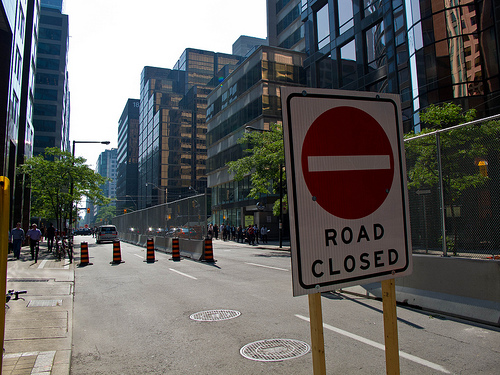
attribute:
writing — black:
[312, 218, 400, 284]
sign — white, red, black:
[277, 82, 417, 299]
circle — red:
[299, 104, 397, 220]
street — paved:
[73, 235, 499, 371]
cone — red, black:
[77, 240, 92, 265]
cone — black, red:
[106, 233, 125, 264]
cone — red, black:
[143, 235, 157, 261]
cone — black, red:
[170, 232, 181, 259]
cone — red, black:
[203, 233, 213, 263]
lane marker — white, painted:
[167, 265, 198, 281]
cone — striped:
[79, 238, 89, 265]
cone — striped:
[109, 238, 125, 265]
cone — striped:
[144, 231, 158, 262]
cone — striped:
[171, 233, 181, 262]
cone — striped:
[199, 236, 216, 260]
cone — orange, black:
[112, 233, 120, 264]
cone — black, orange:
[170, 233, 180, 261]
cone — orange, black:
[195, 231, 217, 271]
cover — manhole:
[193, 308, 238, 329]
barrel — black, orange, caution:
[197, 233, 221, 263]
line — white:
[165, 267, 199, 285]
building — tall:
[137, 34, 265, 231]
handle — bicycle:
[5, 280, 31, 303]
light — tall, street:
[100, 133, 110, 151]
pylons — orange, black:
[75, 241, 94, 269]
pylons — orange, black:
[105, 237, 124, 264]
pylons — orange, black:
[143, 233, 163, 271]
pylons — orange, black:
[168, 236, 183, 263]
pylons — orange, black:
[195, 239, 218, 269]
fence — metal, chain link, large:
[105, 189, 215, 263]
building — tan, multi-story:
[195, 39, 320, 251]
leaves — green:
[51, 163, 58, 170]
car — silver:
[94, 220, 126, 250]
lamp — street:
[62, 128, 111, 237]